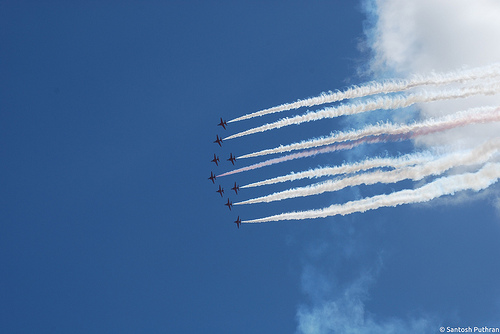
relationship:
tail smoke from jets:
[214, 0, 499, 333] [205, 110, 245, 232]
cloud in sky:
[294, 3, 499, 334] [0, 14, 496, 328]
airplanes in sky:
[198, 103, 255, 233] [0, 14, 496, 328]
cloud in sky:
[357, 3, 499, 155] [0, 14, 496, 328]